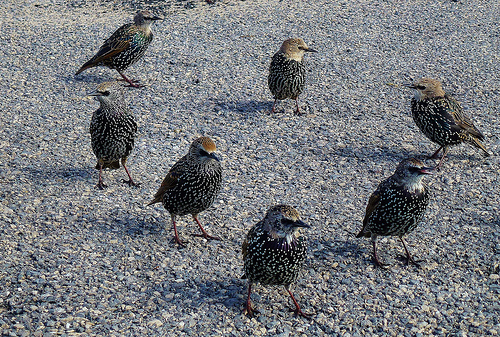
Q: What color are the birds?
A: Black, brown and white.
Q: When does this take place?
A: Daytime.